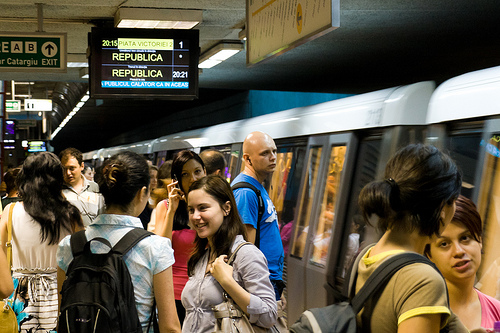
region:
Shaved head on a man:
[219, 122, 304, 192]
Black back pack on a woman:
[54, 225, 182, 323]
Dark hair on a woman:
[349, 123, 499, 265]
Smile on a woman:
[172, 162, 255, 255]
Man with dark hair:
[48, 138, 137, 243]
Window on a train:
[285, 133, 373, 273]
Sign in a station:
[79, 33, 226, 97]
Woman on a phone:
[150, 151, 227, 220]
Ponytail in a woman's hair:
[343, 161, 420, 241]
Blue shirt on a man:
[217, 163, 319, 289]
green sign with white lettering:
[1, 30, 66, 68]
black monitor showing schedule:
[88, 27, 201, 104]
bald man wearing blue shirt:
[229, 130, 286, 300]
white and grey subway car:
[62, 66, 499, 330]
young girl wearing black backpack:
[51, 150, 181, 331]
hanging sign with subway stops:
[244, 0, 341, 67]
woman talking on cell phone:
[165, 148, 208, 240]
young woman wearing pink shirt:
[426, 195, 499, 330]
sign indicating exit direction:
[38, 33, 62, 69]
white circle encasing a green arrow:
[41, 40, 58, 56]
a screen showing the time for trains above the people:
[81, 27, 197, 98]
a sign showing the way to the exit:
[2, 30, 72, 70]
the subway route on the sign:
[243, 0, 341, 60]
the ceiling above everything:
[7, 3, 499, 110]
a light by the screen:
[116, 12, 206, 36]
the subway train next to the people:
[77, 60, 497, 330]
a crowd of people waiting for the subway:
[6, 147, 287, 331]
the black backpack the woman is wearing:
[60, 222, 142, 330]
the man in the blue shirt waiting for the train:
[223, 136, 292, 311]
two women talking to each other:
[313, 147, 497, 329]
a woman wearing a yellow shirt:
[347, 151, 472, 331]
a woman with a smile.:
[175, 167, 280, 329]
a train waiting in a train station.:
[66, 54, 498, 331]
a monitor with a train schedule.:
[87, 13, 204, 110]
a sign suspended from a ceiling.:
[0, 31, 71, 90]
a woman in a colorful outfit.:
[0, 148, 100, 331]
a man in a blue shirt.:
[216, 129, 298, 303]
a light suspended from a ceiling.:
[200, 20, 266, 84]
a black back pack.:
[57, 219, 167, 331]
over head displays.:
[1, 90, 78, 161]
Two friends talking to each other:
[57, 148, 271, 331]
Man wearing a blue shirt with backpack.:
[222, 128, 286, 288]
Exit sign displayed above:
[1, 27, 66, 72]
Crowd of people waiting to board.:
[2, 140, 497, 327]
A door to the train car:
[287, 133, 350, 329]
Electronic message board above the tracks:
[82, 21, 203, 103]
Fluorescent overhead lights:
[46, 83, 91, 142]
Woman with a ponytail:
[345, 143, 460, 249]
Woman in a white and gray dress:
[0, 150, 70, 330]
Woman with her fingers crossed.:
[162, 144, 208, 331]